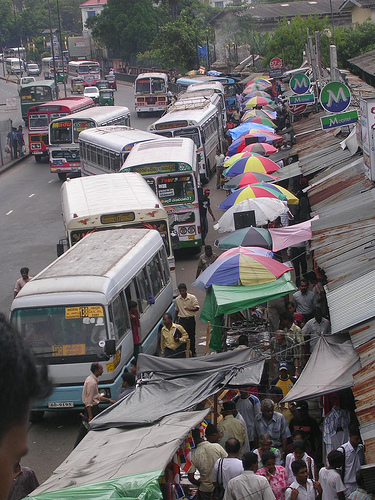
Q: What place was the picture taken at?
A: It was taken at the street.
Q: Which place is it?
A: It is a street.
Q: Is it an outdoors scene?
A: Yes, it is outdoors.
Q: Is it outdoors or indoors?
A: It is outdoors.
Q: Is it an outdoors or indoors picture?
A: It is outdoors.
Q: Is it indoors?
A: No, it is outdoors.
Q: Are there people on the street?
A: Yes, there are people on the street.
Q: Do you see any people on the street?
A: Yes, there are people on the street.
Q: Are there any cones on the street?
A: No, there are people on the street.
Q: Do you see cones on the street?
A: No, there are people on the street.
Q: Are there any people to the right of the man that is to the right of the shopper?
A: Yes, there are people to the right of the man.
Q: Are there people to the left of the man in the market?
A: No, the people are to the right of the man.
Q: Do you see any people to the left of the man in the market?
A: No, the people are to the right of the man.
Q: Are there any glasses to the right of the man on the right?
A: No, there are people to the right of the man.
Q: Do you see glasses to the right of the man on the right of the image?
A: No, there are people to the right of the man.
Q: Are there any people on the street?
A: Yes, there are people on the street.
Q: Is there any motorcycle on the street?
A: No, there are people on the street.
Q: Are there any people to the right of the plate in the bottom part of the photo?
A: Yes, there are people to the right of the plate.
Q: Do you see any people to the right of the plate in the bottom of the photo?
A: Yes, there are people to the right of the plate.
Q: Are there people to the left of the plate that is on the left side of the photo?
A: No, the people are to the right of the plate.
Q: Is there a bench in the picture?
A: No, there are no benches.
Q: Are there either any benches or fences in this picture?
A: No, there are no benches or fences.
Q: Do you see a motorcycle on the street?
A: No, there are people on the street.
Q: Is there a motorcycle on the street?
A: No, there are people on the street.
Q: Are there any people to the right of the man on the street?
A: Yes, there are people to the right of the man.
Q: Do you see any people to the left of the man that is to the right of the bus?
A: No, the people are to the right of the man.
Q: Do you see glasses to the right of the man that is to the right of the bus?
A: No, there are people to the right of the man.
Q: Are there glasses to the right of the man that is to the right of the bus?
A: No, there are people to the right of the man.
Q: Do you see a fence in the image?
A: No, there are no fences.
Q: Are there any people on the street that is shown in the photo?
A: Yes, there are people on the street.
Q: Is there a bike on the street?
A: No, there are people on the street.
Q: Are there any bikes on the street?
A: No, there are people on the street.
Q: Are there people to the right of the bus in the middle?
A: Yes, there are people to the right of the bus.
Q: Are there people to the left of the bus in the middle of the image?
A: No, the people are to the right of the bus.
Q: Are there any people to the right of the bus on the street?
A: Yes, there are people to the right of the bus.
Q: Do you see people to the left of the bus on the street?
A: No, the people are to the right of the bus.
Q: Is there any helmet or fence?
A: No, there are no fences or helmets.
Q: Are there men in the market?
A: Yes, there is a man in the market.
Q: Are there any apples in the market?
A: No, there is a man in the market.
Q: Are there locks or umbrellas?
A: Yes, there is an umbrella.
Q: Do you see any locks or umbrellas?
A: Yes, there is an umbrella.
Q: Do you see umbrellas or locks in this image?
A: Yes, there is an umbrella.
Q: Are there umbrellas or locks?
A: Yes, there is an umbrella.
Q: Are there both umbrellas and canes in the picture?
A: No, there is an umbrella but no canes.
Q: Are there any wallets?
A: No, there are no wallets.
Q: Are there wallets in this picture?
A: No, there are no wallets.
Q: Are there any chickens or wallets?
A: No, there are no wallets or chickens.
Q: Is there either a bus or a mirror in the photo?
A: Yes, there is a bus.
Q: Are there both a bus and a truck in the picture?
A: No, there is a bus but no trucks.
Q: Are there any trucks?
A: No, there are no trucks.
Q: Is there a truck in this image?
A: No, there are no trucks.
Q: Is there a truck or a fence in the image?
A: No, there are no trucks or fences.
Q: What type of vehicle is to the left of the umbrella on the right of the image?
A: The vehicle is a bus.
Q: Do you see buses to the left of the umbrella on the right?
A: Yes, there is a bus to the left of the umbrella.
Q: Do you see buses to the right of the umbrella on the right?
A: No, the bus is to the left of the umbrella.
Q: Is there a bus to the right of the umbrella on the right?
A: No, the bus is to the left of the umbrella.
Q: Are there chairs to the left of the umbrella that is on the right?
A: No, there is a bus to the left of the umbrella.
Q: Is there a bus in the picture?
A: Yes, there is a bus.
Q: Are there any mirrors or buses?
A: Yes, there is a bus.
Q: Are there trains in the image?
A: No, there are no trains.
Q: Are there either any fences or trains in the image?
A: No, there are no trains or fences.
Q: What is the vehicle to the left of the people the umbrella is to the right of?
A: The vehicle is a bus.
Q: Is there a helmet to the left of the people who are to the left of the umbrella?
A: No, there is a bus to the left of the people.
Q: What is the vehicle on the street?
A: The vehicle is a bus.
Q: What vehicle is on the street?
A: The vehicle is a bus.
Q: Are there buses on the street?
A: Yes, there is a bus on the street.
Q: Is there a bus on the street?
A: Yes, there is a bus on the street.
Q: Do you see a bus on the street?
A: Yes, there is a bus on the street.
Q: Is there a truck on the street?
A: No, there is a bus on the street.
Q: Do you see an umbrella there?
A: Yes, there is an umbrella.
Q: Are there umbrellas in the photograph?
A: Yes, there is an umbrella.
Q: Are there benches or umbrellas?
A: Yes, there is an umbrella.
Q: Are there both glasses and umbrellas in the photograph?
A: No, there is an umbrella but no glasses.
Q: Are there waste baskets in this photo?
A: No, there are no waste baskets.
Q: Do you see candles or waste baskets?
A: No, there are no waste baskets or candles.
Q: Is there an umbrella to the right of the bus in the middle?
A: Yes, there is an umbrella to the right of the bus.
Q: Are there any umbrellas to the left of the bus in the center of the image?
A: No, the umbrella is to the right of the bus.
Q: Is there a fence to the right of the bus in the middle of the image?
A: No, there is an umbrella to the right of the bus.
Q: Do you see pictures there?
A: No, there are no pictures.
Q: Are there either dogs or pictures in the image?
A: No, there are no pictures or dogs.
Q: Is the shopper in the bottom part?
A: Yes, the shopper is in the bottom of the image.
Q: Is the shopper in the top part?
A: No, the shopper is in the bottom of the image.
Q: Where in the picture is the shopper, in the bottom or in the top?
A: The shopper is in the bottom of the image.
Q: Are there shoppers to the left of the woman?
A: Yes, there is a shopper to the left of the woman.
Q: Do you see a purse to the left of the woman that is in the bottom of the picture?
A: No, there is a shopper to the left of the woman.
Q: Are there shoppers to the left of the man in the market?
A: Yes, there is a shopper to the left of the man.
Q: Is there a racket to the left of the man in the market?
A: No, there is a shopper to the left of the man.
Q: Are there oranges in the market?
A: No, there is a shopper in the market.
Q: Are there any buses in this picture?
A: Yes, there is a bus.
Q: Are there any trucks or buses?
A: Yes, there is a bus.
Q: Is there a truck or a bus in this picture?
A: Yes, there is a bus.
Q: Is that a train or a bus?
A: That is a bus.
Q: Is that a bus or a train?
A: That is a bus.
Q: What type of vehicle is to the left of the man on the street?
A: The vehicle is a bus.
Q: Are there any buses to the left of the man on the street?
A: Yes, there is a bus to the left of the man.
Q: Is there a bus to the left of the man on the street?
A: Yes, there is a bus to the left of the man.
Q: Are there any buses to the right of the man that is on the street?
A: No, the bus is to the left of the man.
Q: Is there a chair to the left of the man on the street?
A: No, there is a bus to the left of the man.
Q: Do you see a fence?
A: No, there are no fences.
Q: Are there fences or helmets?
A: No, there are no fences or helmets.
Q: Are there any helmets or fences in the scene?
A: No, there are no fences or helmets.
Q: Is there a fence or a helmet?
A: No, there are no fences or helmets.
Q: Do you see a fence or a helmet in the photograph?
A: No, there are no fences or helmets.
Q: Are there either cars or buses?
A: Yes, there is a bus.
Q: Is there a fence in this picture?
A: No, there are no fences.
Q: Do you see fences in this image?
A: No, there are no fences.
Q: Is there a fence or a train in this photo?
A: No, there are no fences or trains.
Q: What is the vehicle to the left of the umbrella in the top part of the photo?
A: The vehicle is a bus.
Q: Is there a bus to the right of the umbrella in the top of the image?
A: No, the bus is to the left of the umbrella.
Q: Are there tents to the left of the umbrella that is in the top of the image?
A: No, there is a bus to the left of the umbrella.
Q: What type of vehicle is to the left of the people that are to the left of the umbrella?
A: The vehicle is a bus.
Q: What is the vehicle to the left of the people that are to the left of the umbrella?
A: The vehicle is a bus.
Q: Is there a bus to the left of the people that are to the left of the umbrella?
A: Yes, there is a bus to the left of the people.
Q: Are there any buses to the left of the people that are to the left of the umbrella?
A: Yes, there is a bus to the left of the people.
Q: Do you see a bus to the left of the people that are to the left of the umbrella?
A: Yes, there is a bus to the left of the people.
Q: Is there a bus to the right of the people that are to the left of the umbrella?
A: No, the bus is to the left of the people.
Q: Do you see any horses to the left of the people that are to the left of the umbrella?
A: No, there is a bus to the left of the people.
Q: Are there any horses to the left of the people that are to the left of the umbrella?
A: No, there is a bus to the left of the people.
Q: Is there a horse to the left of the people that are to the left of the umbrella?
A: No, there is a bus to the left of the people.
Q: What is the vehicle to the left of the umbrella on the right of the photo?
A: The vehicle is a bus.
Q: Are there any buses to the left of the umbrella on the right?
A: Yes, there is a bus to the left of the umbrella.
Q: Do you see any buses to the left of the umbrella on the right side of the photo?
A: Yes, there is a bus to the left of the umbrella.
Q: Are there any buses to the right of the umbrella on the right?
A: No, the bus is to the left of the umbrella.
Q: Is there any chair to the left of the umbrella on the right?
A: No, there is a bus to the left of the umbrella.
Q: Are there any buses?
A: Yes, there is a bus.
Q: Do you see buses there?
A: Yes, there is a bus.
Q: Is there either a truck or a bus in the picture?
A: Yes, there is a bus.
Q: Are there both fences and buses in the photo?
A: No, there is a bus but no fences.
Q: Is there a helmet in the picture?
A: No, there are no helmets.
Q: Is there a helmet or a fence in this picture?
A: No, there are no helmets or fences.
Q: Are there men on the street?
A: Yes, there is a man on the street.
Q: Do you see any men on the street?
A: Yes, there is a man on the street.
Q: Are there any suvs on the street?
A: No, there is a man on the street.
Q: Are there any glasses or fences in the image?
A: No, there are no fences or glasses.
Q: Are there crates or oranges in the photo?
A: No, there are no oranges or crates.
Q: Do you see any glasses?
A: No, there are no glasses.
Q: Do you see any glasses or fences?
A: No, there are no glasses or fences.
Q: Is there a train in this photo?
A: No, there are no trains.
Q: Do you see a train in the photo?
A: No, there are no trains.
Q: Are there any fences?
A: No, there are no fences.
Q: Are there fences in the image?
A: No, there are no fences.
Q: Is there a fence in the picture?
A: No, there are no fences.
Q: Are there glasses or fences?
A: No, there are no fences or glasses.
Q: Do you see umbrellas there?
A: Yes, there is an umbrella.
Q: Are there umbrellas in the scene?
A: Yes, there is an umbrella.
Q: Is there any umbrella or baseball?
A: Yes, there is an umbrella.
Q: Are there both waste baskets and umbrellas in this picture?
A: No, there is an umbrella but no waste baskets.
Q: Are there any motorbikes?
A: No, there are no motorbikes.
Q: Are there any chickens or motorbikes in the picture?
A: No, there are no motorbikes or chickens.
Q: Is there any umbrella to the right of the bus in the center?
A: Yes, there is an umbrella to the right of the bus.